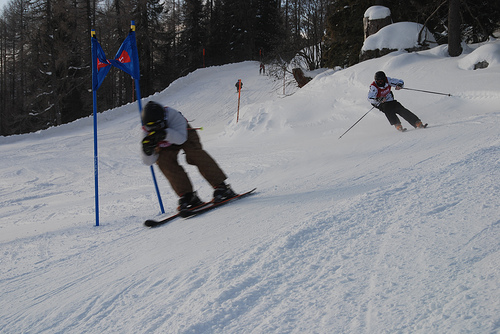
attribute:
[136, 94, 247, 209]
person —  bent over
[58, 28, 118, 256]
flag — yellow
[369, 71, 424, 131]
skier —  leaning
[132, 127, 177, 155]
hands —  raised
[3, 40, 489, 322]
snow — white,  fluffy,  white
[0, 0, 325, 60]
sky —  streaks 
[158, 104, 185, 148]
shirt —  white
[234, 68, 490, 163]
smooth snow —  smooth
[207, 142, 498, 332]
rough snow —  rough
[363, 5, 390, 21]
snow —  in domes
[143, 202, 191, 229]
ski — pair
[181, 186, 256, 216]
ski — pair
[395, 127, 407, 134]
ski — pair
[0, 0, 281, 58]
trees —  some,  in background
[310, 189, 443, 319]
snow — white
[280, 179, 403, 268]
snow — white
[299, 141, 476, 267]
snow — white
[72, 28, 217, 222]
flat —  blue and red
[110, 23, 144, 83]
flag — blue and red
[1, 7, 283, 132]
branches —   dense